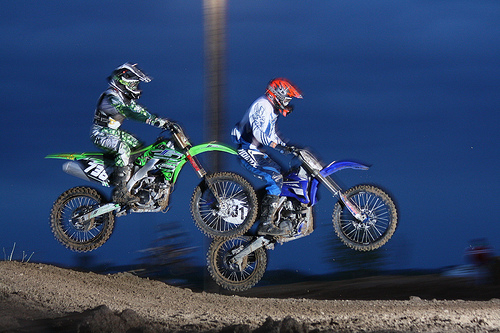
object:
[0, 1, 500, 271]
sky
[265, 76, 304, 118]
helmet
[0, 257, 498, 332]
ground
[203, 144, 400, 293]
motorbike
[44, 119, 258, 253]
motorbike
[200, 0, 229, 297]
pole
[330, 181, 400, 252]
front wheel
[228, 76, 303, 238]
rider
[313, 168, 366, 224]
suspension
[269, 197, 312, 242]
engine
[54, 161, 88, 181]
tail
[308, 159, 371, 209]
mud guard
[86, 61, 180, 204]
rider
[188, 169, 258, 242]
front wheel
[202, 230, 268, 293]
back wheel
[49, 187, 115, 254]
back wheel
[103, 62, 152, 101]
helmet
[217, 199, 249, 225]
number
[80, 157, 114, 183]
number